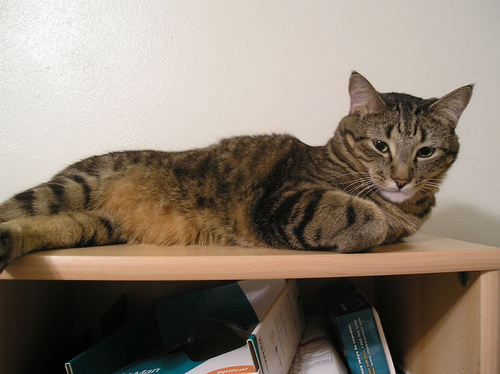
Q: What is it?
A: Cat.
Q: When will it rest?
A: Now.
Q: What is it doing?
A: Resting.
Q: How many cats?
A: 1.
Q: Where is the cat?
A: Shelf.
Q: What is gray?
A: The cat.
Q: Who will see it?
A: People.